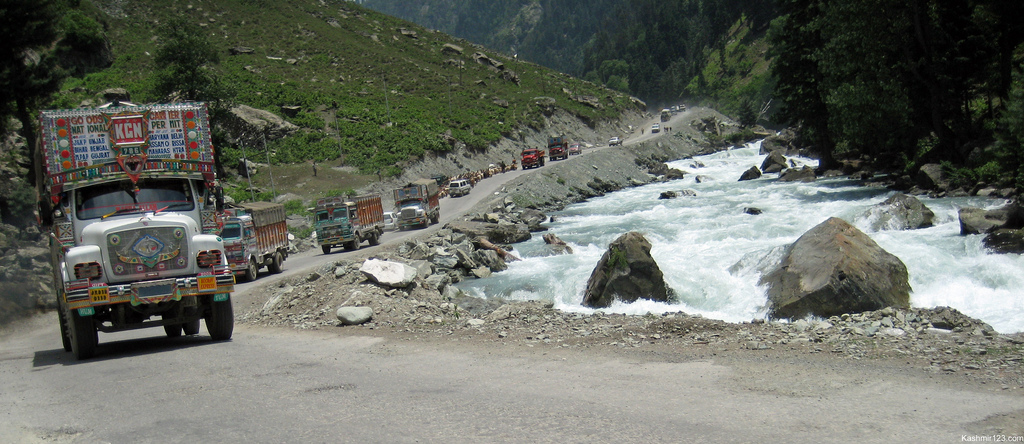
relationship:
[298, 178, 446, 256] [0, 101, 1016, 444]
cars are all on mountain road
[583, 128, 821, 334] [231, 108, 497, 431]
river next to road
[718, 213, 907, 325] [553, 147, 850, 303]
boulder in water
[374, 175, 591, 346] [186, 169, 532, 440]
rocks on side of road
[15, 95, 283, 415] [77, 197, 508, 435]
car on a street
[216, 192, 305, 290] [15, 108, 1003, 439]
car on street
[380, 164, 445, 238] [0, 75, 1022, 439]
car on street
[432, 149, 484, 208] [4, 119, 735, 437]
car on street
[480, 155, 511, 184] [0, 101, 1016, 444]
car on mountain road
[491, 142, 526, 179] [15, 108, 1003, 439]
car on street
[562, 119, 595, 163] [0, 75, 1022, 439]
car on street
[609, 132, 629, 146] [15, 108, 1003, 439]
car on street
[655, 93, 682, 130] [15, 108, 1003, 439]
car on street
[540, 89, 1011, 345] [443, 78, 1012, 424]
water rushing down river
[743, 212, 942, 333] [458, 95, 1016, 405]
boulder in river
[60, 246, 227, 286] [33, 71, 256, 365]
front lights on truck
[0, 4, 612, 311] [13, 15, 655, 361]
grass covering mountainside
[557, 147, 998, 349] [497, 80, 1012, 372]
caps in water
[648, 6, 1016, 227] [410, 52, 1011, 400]
tree covering river bank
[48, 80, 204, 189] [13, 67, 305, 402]
advertisement covering top truck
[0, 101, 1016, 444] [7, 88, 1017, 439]
mountain road on mountain road